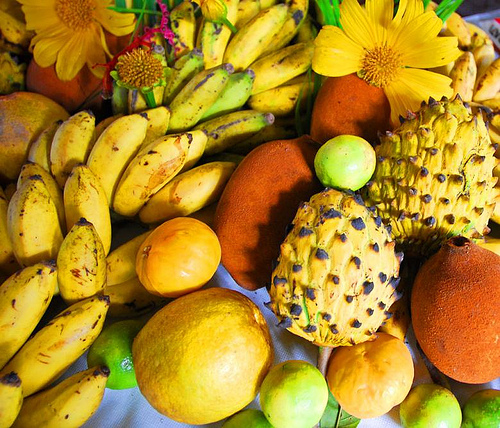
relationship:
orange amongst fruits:
[125, 282, 278, 427] [1, 0, 497, 426]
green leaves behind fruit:
[310, 0, 346, 27] [8, 70, 494, 396]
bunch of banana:
[58, 153, 130, 428] [109, 131, 196, 219]